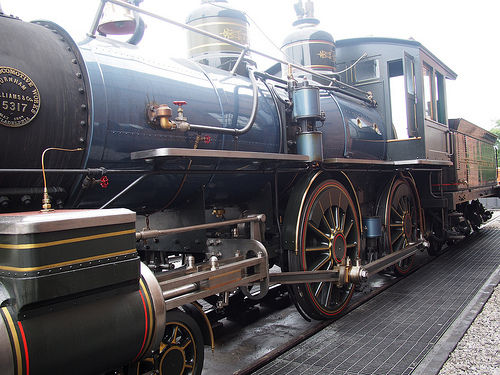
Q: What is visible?
A: A train.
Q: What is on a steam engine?
A: A wheel.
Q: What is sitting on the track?
A: The train.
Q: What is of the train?
A: A wheel.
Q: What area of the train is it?
A: Fuel.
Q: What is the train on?
A: Tracks.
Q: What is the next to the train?
A: A sidewalk.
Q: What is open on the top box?
A: A door.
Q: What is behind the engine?
A: A train car.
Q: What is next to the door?
A: Windows.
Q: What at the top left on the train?
A: A plaque.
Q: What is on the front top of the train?
A: A bell.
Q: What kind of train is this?
A: A steam engine.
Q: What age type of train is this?
A: A vintage train.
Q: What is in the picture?
A: Train.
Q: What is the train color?
A: Blue.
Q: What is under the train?
A: Wheels.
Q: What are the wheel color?
A: Red and black.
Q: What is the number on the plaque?
A: 5317.